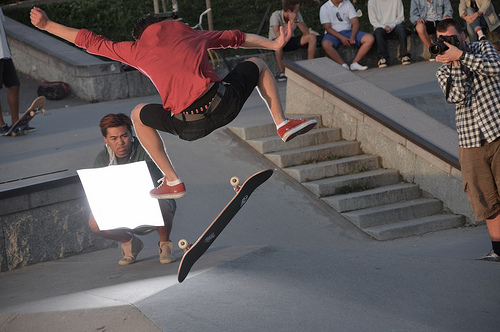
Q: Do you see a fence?
A: No, there are no fences.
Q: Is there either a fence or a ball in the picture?
A: No, there are no fences or balls.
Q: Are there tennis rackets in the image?
A: No, there are no tennis rackets.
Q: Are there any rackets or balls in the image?
A: No, there are no rackets or balls.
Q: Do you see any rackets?
A: No, there are no rackets.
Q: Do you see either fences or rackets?
A: No, there are no rackets or fences.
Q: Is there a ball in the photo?
A: No, there are no balls.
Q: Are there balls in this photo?
A: No, there are no balls.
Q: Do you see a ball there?
A: No, there are no balls.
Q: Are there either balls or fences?
A: No, there are no balls or fences.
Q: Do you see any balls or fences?
A: No, there are no balls or fences.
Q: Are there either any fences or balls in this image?
A: No, there are no balls or fences.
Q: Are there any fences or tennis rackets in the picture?
A: No, there are no fences or tennis rackets.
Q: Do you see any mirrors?
A: Yes, there is a mirror.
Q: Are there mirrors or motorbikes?
A: Yes, there is a mirror.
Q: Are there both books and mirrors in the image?
A: No, there is a mirror but no books.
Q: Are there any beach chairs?
A: No, there are no beach chairs.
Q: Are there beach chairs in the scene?
A: No, there are no beach chairs.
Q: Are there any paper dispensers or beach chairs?
A: No, there are no beach chairs or paper dispensers.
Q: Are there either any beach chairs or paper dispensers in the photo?
A: No, there are no beach chairs or paper dispensers.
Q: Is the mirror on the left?
A: Yes, the mirror is on the left of the image.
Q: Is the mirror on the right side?
A: No, the mirror is on the left of the image.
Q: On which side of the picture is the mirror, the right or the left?
A: The mirror is on the left of the image.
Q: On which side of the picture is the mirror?
A: The mirror is on the left of the image.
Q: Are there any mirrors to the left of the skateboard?
A: Yes, there is a mirror to the left of the skateboard.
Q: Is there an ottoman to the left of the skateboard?
A: No, there is a mirror to the left of the skateboard.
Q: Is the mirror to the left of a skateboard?
A: Yes, the mirror is to the left of a skateboard.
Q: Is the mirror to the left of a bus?
A: No, the mirror is to the left of a skateboard.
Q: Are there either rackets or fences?
A: No, there are no fences or rackets.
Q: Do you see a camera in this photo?
A: Yes, there is a camera.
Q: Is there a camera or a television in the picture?
A: Yes, there is a camera.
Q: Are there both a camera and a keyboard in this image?
A: No, there is a camera but no keyboards.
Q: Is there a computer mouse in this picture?
A: No, there are no computer mice.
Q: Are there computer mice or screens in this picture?
A: No, there are no computer mice or screens.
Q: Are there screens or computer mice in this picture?
A: No, there are no computer mice or screens.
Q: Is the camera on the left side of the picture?
A: No, the camera is on the right of the image.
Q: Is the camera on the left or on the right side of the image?
A: The camera is on the right of the image.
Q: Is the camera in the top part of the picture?
A: Yes, the camera is in the top of the image.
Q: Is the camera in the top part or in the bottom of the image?
A: The camera is in the top of the image.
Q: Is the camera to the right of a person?
A: Yes, the camera is to the right of a person.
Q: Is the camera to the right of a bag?
A: No, the camera is to the right of a person.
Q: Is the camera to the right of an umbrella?
A: No, the camera is to the right of a man.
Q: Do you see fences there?
A: No, there are no fences.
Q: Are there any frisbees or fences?
A: No, there are no fences or frisbees.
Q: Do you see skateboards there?
A: Yes, there is a skateboard.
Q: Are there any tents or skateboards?
A: Yes, there is a skateboard.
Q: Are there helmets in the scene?
A: No, there are no helmets.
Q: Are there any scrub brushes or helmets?
A: No, there are no helmets or scrub brushes.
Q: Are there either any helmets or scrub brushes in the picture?
A: No, there are no helmets or scrub brushes.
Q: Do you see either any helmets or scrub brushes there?
A: No, there are no helmets or scrub brushes.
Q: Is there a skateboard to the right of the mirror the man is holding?
A: Yes, there is a skateboard to the right of the mirror.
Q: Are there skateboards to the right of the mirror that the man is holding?
A: Yes, there is a skateboard to the right of the mirror.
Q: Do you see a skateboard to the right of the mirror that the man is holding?
A: Yes, there is a skateboard to the right of the mirror.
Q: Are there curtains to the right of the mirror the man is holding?
A: No, there is a skateboard to the right of the mirror.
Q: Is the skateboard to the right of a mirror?
A: Yes, the skateboard is to the right of a mirror.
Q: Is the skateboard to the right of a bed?
A: No, the skateboard is to the right of a mirror.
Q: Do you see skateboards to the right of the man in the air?
A: Yes, there is a skateboard to the right of the man.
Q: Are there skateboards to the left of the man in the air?
A: No, the skateboard is to the right of the man.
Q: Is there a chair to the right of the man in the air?
A: No, there is a skateboard to the right of the man.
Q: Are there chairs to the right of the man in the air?
A: No, there is a skateboard to the right of the man.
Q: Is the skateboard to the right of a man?
A: Yes, the skateboard is to the right of a man.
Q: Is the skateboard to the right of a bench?
A: No, the skateboard is to the right of a man.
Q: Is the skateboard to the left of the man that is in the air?
A: No, the skateboard is to the right of the man.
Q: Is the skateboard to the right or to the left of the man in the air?
A: The skateboard is to the right of the man.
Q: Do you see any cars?
A: No, there are no cars.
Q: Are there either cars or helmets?
A: No, there are no cars or helmets.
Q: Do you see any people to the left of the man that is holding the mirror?
A: Yes, there is a person to the left of the man.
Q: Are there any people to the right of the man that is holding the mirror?
A: No, the person is to the left of the man.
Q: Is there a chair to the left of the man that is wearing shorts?
A: No, there is a person to the left of the man.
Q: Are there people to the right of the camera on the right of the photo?
A: No, the person is to the left of the camera.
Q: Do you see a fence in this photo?
A: No, there are no fences.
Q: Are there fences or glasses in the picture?
A: No, there are no fences or glasses.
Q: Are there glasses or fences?
A: No, there are no fences or glasses.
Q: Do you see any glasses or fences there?
A: No, there are no fences or glasses.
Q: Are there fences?
A: No, there are no fences.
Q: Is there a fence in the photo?
A: No, there are no fences.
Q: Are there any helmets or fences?
A: No, there are no fences or helmets.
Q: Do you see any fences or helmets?
A: No, there are no fences or helmets.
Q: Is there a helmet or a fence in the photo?
A: No, there are no fences or helmets.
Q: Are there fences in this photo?
A: No, there are no fences.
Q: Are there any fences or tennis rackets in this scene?
A: No, there are no fences or tennis rackets.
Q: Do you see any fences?
A: No, there are no fences.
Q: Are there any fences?
A: No, there are no fences.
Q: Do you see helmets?
A: No, there are no helmets.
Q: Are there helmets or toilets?
A: No, there are no helmets or toilets.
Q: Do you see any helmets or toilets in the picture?
A: No, there are no helmets or toilets.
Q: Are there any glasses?
A: No, there are no glasses.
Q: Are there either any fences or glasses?
A: No, there are no glasses or fences.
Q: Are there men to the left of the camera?
A: Yes, there is a man to the left of the camera.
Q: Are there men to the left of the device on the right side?
A: Yes, there is a man to the left of the camera.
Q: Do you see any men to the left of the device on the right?
A: Yes, there is a man to the left of the camera.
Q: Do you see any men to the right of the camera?
A: No, the man is to the left of the camera.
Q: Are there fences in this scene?
A: No, there are no fences.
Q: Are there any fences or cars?
A: No, there are no fences or cars.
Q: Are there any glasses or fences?
A: No, there are no glasses or fences.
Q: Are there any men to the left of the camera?
A: Yes, there is a man to the left of the camera.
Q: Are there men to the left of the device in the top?
A: Yes, there is a man to the left of the camera.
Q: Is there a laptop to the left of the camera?
A: No, there is a man to the left of the camera.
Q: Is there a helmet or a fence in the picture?
A: No, there are no fences or helmets.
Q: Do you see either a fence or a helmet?
A: No, there are no fences or helmets.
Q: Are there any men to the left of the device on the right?
A: Yes, there is a man to the left of the camera.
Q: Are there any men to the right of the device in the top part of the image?
A: No, the man is to the left of the camera.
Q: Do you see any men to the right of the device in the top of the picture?
A: No, the man is to the left of the camera.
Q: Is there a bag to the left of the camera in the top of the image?
A: No, there is a man to the left of the camera.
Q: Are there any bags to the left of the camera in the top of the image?
A: No, there is a man to the left of the camera.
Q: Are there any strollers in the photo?
A: No, there are no strollers.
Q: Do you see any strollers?
A: No, there are no strollers.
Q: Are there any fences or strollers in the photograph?
A: No, there are no strollers or fences.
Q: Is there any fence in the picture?
A: No, there are no fences.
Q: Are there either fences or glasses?
A: No, there are no fences or glasses.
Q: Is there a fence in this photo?
A: No, there are no fences.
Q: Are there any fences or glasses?
A: No, there are no glasses or fences.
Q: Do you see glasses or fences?
A: No, there are no glasses or fences.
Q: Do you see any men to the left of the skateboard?
A: Yes, there is a man to the left of the skateboard.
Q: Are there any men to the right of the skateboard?
A: No, the man is to the left of the skateboard.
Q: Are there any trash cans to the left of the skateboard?
A: No, there is a man to the left of the skateboard.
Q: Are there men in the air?
A: Yes, there is a man in the air.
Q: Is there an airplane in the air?
A: No, there is a man in the air.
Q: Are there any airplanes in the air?
A: No, there is a man in the air.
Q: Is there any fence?
A: No, there are no fences.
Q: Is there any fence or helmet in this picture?
A: No, there are no fences or helmets.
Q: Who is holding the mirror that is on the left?
A: The man is holding the mirror.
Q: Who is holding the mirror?
A: The man is holding the mirror.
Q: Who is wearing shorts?
A: The man is wearing shorts.